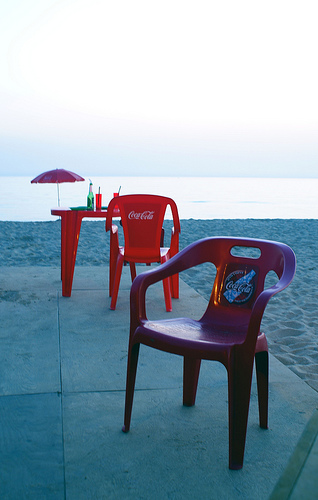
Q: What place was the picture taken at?
A: It was taken at the beach.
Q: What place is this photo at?
A: It is at the beach.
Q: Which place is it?
A: It is a beach.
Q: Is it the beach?
A: Yes, it is the beach.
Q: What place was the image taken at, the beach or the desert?
A: It was taken at the beach.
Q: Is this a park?
A: No, it is a beach.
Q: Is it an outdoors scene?
A: Yes, it is outdoors.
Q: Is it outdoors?
A: Yes, it is outdoors.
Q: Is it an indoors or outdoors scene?
A: It is outdoors.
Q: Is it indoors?
A: No, it is outdoors.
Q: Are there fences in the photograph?
A: No, there are no fences.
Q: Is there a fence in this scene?
A: No, there are no fences.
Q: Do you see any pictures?
A: No, there are no pictures.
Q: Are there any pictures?
A: No, there are no pictures.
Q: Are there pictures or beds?
A: No, there are no pictures or beds.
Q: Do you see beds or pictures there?
A: No, there are no pictures or beds.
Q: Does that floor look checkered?
A: Yes, the floor is checkered.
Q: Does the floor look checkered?
A: Yes, the floor is checkered.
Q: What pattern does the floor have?
A: The floor has checkered pattern.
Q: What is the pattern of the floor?
A: The floor is checkered.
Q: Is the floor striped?
A: No, the floor is checkered.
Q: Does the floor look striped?
A: No, the floor is checkered.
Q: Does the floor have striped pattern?
A: No, the floor is checkered.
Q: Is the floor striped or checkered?
A: The floor is checkered.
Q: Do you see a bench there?
A: No, there are no benches.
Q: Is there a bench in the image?
A: No, there are no benches.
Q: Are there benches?
A: No, there are no benches.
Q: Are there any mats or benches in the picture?
A: No, there are no benches or mats.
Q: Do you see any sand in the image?
A: Yes, there is sand.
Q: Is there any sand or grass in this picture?
A: Yes, there is sand.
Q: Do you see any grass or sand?
A: Yes, there is sand.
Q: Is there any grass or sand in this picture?
A: Yes, there is sand.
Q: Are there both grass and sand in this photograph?
A: No, there is sand but no grass.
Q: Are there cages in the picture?
A: No, there are no cages.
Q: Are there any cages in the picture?
A: No, there are no cages.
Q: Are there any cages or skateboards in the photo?
A: No, there are no cages or skateboards.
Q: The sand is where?
A: The sand is on the beach.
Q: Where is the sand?
A: The sand is on the beach.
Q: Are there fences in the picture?
A: No, there are no fences.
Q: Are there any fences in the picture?
A: No, there are no fences.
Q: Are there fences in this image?
A: No, there are no fences.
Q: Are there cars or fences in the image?
A: No, there are no fences or cars.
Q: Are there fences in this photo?
A: No, there are no fences.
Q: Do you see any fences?
A: No, there are no fences.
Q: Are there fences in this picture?
A: No, there are no fences.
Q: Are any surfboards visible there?
A: No, there are no surfboards.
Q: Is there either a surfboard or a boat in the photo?
A: No, there are no surfboards or boats.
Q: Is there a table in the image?
A: Yes, there is a table.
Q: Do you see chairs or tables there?
A: Yes, there is a table.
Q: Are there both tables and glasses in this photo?
A: No, there is a table but no glasses.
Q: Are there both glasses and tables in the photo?
A: No, there is a table but no glasses.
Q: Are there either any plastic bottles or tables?
A: Yes, there is a plastic table.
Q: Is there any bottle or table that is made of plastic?
A: Yes, the table is made of plastic.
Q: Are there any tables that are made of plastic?
A: Yes, there is a table that is made of plastic.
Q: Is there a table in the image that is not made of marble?
A: Yes, there is a table that is made of plastic.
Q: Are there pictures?
A: No, there are no pictures.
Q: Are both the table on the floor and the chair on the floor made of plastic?
A: Yes, both the table and the chair are made of plastic.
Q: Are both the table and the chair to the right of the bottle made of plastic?
A: Yes, both the table and the chair are made of plastic.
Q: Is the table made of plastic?
A: Yes, the table is made of plastic.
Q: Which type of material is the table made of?
A: The table is made of plastic.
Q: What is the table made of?
A: The table is made of plastic.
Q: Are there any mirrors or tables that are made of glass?
A: No, there is a table but it is made of plastic.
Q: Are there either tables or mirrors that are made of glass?
A: No, there is a table but it is made of plastic.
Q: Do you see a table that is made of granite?
A: No, there is a table but it is made of plastic.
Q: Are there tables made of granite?
A: No, there is a table but it is made of plastic.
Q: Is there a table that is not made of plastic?
A: No, there is a table but it is made of plastic.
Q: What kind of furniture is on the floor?
A: The piece of furniture is a table.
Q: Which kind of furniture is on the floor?
A: The piece of furniture is a table.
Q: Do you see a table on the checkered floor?
A: Yes, there is a table on the floor.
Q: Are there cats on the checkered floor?
A: No, there is a table on the floor.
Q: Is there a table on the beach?
A: Yes, there is a table on the beach.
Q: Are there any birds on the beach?
A: No, there is a table on the beach.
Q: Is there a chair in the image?
A: Yes, there is a chair.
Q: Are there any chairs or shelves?
A: Yes, there is a chair.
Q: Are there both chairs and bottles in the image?
A: Yes, there are both a chair and a bottle.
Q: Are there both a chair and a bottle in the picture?
A: Yes, there are both a chair and a bottle.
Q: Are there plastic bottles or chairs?
A: Yes, there is a plastic chair.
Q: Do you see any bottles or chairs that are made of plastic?
A: Yes, the chair is made of plastic.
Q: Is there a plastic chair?
A: Yes, there is a chair that is made of plastic.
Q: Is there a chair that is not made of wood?
A: Yes, there is a chair that is made of plastic.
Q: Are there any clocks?
A: No, there are no clocks.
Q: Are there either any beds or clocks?
A: No, there are no clocks or beds.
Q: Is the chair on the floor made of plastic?
A: Yes, the chair is made of plastic.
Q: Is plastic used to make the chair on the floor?
A: Yes, the chair is made of plastic.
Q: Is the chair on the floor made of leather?
A: No, the chair is made of plastic.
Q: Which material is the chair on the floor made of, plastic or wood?
A: The chair is made of plastic.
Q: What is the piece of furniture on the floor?
A: The piece of furniture is a chair.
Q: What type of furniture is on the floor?
A: The piece of furniture is a chair.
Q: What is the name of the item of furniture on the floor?
A: The piece of furniture is a chair.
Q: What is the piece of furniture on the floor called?
A: The piece of furniture is a chair.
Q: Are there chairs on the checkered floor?
A: Yes, there is a chair on the floor.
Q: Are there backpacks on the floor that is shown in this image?
A: No, there is a chair on the floor.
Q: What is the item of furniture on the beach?
A: The piece of furniture is a chair.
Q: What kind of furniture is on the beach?
A: The piece of furniture is a chair.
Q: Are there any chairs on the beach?
A: Yes, there is a chair on the beach.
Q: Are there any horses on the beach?
A: No, there is a chair on the beach.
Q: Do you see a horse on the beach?
A: No, there is a chair on the beach.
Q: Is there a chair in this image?
A: Yes, there is a chair.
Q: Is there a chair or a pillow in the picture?
A: Yes, there is a chair.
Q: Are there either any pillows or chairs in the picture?
A: Yes, there is a chair.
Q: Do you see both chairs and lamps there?
A: No, there is a chair but no lamps.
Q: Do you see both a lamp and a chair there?
A: No, there is a chair but no lamps.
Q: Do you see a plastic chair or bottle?
A: Yes, there is a plastic chair.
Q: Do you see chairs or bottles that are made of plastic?
A: Yes, the chair is made of plastic.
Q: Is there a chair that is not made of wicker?
A: Yes, there is a chair that is made of plastic.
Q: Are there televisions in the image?
A: No, there are no televisions.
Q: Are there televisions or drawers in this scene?
A: No, there are no televisions or drawers.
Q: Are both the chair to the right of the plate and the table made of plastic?
A: Yes, both the chair and the table are made of plastic.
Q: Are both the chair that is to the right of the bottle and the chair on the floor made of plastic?
A: Yes, both the chair and the chair are made of plastic.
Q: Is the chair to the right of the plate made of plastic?
A: Yes, the chair is made of plastic.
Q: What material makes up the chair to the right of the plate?
A: The chair is made of plastic.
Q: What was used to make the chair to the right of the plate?
A: The chair is made of plastic.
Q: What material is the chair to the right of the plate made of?
A: The chair is made of plastic.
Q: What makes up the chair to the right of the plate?
A: The chair is made of plastic.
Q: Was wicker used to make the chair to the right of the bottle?
A: No, the chair is made of plastic.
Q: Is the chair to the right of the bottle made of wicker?
A: No, the chair is made of plastic.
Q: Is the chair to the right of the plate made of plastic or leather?
A: The chair is made of plastic.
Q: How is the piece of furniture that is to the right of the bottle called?
A: The piece of furniture is a chair.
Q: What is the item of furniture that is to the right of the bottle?
A: The piece of furniture is a chair.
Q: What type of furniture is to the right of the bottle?
A: The piece of furniture is a chair.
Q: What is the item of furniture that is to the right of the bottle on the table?
A: The piece of furniture is a chair.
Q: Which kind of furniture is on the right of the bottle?
A: The piece of furniture is a chair.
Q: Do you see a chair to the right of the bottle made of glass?
A: Yes, there is a chair to the right of the bottle.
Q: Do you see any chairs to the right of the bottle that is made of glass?
A: Yes, there is a chair to the right of the bottle.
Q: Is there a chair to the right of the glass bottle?
A: Yes, there is a chair to the right of the bottle.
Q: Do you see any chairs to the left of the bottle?
A: No, the chair is to the right of the bottle.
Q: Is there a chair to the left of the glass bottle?
A: No, the chair is to the right of the bottle.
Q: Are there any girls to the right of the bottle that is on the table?
A: No, there is a chair to the right of the bottle.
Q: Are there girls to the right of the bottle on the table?
A: No, there is a chair to the right of the bottle.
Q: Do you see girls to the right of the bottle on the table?
A: No, there is a chair to the right of the bottle.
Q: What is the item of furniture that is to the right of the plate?
A: The piece of furniture is a chair.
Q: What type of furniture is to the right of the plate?
A: The piece of furniture is a chair.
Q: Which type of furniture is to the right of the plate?
A: The piece of furniture is a chair.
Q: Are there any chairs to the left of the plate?
A: No, the chair is to the right of the plate.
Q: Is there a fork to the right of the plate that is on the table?
A: No, there is a chair to the right of the plate.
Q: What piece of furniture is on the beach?
A: The piece of furniture is a chair.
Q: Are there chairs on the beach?
A: Yes, there is a chair on the beach.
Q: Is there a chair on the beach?
A: Yes, there is a chair on the beach.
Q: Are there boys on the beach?
A: No, there is a chair on the beach.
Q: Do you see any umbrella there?
A: Yes, there is an umbrella.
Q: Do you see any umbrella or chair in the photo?
A: Yes, there is an umbrella.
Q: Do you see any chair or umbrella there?
A: Yes, there is an umbrella.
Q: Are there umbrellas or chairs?
A: Yes, there is an umbrella.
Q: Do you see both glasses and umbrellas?
A: No, there is an umbrella but no glasses.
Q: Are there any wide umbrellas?
A: Yes, there is a wide umbrella.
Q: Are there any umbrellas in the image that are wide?
A: Yes, there is an umbrella that is wide.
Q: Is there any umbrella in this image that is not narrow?
A: Yes, there is a wide umbrella.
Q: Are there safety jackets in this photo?
A: No, there are no safety jackets.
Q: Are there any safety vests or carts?
A: No, there are no safety vests or carts.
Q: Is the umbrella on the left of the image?
A: Yes, the umbrella is on the left of the image.